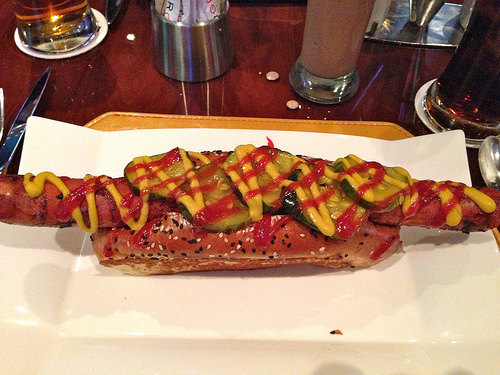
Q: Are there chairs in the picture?
A: No, there are no chairs.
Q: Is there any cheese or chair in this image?
A: No, there are no chairs or cheese.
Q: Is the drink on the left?
A: Yes, the drink is on the left of the image.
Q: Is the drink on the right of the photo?
A: No, the drink is on the left of the image.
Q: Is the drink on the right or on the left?
A: The drink is on the left of the image.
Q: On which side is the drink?
A: The drink is on the left of the image.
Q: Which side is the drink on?
A: The drink is on the left of the image.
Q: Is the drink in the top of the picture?
A: Yes, the drink is in the top of the image.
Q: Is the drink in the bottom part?
A: No, the drink is in the top of the image.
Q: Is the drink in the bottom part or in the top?
A: The drink is in the top of the image.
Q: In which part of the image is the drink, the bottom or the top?
A: The drink is in the top of the image.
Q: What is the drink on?
A: The drink is on the table.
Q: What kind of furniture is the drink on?
A: The drink is on the table.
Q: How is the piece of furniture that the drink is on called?
A: The piece of furniture is a table.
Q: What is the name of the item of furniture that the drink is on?
A: The piece of furniture is a table.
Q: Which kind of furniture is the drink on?
A: The drink is on the table.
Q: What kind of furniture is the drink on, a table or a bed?
A: The drink is on a table.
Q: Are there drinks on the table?
A: Yes, there is a drink on the table.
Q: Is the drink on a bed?
A: No, the drink is on the table.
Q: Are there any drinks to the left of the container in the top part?
A: Yes, there is a drink to the left of the container.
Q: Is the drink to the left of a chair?
A: No, the drink is to the left of the container.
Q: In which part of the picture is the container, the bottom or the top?
A: The container is in the top of the image.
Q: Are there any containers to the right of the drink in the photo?
A: Yes, there is a container to the right of the drink.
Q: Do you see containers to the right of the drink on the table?
A: Yes, there is a container to the right of the drink.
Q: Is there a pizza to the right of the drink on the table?
A: No, there is a container to the right of the drink.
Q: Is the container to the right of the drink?
A: Yes, the container is to the right of the drink.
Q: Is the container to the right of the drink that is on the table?
A: Yes, the container is to the right of the drink.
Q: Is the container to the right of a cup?
A: No, the container is to the right of the drink.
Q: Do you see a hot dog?
A: Yes, there is a hot dog.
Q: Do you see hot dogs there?
A: Yes, there is a hot dog.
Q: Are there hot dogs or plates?
A: Yes, there is a hot dog.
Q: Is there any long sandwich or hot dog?
A: Yes, there is a long hot dog.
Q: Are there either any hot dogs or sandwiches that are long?
A: Yes, the hot dog is long.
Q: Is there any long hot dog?
A: Yes, there is a long hot dog.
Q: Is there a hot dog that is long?
A: Yes, there is a hot dog that is long.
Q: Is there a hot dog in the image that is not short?
A: Yes, there is a long hot dog.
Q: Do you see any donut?
A: No, there are no donuts.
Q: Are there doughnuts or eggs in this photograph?
A: No, there are no doughnuts or eggs.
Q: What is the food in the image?
A: The food is a hot dog.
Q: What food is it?
A: The food is a hot dog.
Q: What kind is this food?
A: This is a hot dog.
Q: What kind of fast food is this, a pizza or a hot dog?
A: This is a hot dog.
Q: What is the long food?
A: The food is a hot dog.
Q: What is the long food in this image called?
A: The food is a hot dog.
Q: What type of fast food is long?
A: The fast food is a hot dog.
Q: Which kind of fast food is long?
A: The fast food is a hot dog.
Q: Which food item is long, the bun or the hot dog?
A: The hot dog is long.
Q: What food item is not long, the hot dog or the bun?
A: The bun is not long.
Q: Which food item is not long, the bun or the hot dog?
A: The bun is not long.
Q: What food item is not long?
A: The food item is a bun.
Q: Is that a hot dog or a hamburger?
A: That is a hot dog.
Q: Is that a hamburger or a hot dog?
A: That is a hot dog.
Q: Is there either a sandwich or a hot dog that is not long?
A: No, there is a hot dog but it is long.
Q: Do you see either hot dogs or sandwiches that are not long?
A: No, there is a hot dog but it is long.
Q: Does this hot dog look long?
A: Yes, the hot dog is long.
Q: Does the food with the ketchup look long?
A: Yes, the hot dog is long.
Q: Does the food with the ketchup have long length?
A: Yes, the hot dog is long.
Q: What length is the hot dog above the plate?
A: The hot dog is long.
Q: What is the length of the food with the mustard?
A: The hot dog is long.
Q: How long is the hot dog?
A: The hot dog is long.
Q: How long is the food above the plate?
A: The hot dog is long.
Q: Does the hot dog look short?
A: No, the hot dog is long.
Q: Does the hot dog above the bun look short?
A: No, the hot dog is long.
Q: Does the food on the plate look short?
A: No, the hot dog is long.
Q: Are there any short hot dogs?
A: No, there is a hot dog but it is long.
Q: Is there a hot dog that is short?
A: No, there is a hot dog but it is long.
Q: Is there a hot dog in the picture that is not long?
A: No, there is a hot dog but it is long.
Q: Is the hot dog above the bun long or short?
A: The hot dog is long.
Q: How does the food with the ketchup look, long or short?
A: The hot dog is long.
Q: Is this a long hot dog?
A: Yes, this is a long hot dog.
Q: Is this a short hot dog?
A: No, this is a long hot dog.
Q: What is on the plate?
A: The hot dog is on the plate.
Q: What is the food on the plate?
A: The food is a hot dog.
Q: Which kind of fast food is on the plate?
A: The food is a hot dog.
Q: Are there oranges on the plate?
A: No, there is a hot dog on the plate.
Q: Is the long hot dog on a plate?
A: Yes, the hot dog is on a plate.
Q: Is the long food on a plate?
A: Yes, the hot dog is on a plate.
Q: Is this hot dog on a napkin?
A: No, the hot dog is on a plate.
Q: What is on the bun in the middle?
A: The hot dog is on the bun.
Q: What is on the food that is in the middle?
A: The hot dog is on the bun.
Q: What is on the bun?
A: The hot dog is on the bun.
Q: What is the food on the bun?
A: The food is a hot dog.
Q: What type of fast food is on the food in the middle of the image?
A: The food is a hot dog.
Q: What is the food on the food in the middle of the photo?
A: The food is a hot dog.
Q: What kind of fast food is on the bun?
A: The food is a hot dog.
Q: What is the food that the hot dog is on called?
A: The food is a bun.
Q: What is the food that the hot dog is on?
A: The food is a bun.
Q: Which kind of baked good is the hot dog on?
A: The hot dog is on the bun.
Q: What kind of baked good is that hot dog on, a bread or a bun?
A: The hot dog is on a bun.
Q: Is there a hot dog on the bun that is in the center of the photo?
A: Yes, there is a hot dog on the bun.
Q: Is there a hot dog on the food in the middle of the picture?
A: Yes, there is a hot dog on the bun.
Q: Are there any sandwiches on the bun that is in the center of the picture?
A: No, there is a hot dog on the bun.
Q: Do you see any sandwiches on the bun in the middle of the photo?
A: No, there is a hot dog on the bun.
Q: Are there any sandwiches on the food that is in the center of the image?
A: No, there is a hot dog on the bun.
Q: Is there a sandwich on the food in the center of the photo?
A: No, there is a hot dog on the bun.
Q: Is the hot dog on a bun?
A: Yes, the hot dog is on a bun.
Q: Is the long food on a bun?
A: Yes, the hot dog is on a bun.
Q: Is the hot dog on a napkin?
A: No, the hot dog is on a bun.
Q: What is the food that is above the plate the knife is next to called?
A: The food is a hot dog.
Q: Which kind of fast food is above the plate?
A: The food is a hot dog.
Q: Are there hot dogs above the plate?
A: Yes, there is a hot dog above the plate.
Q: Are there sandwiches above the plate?
A: No, there is a hot dog above the plate.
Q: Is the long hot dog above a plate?
A: Yes, the hot dog is above a plate.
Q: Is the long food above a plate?
A: Yes, the hot dog is above a plate.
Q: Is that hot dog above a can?
A: No, the hot dog is above a plate.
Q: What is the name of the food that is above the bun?
A: The food is a hot dog.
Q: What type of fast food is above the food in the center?
A: The food is a hot dog.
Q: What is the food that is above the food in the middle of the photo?
A: The food is a hot dog.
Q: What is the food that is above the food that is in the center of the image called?
A: The food is a hot dog.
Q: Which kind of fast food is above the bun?
A: The food is a hot dog.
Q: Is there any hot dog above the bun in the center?
A: Yes, there is a hot dog above the bun.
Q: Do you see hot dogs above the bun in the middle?
A: Yes, there is a hot dog above the bun.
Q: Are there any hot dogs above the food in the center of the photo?
A: Yes, there is a hot dog above the bun.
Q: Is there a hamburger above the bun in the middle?
A: No, there is a hot dog above the bun.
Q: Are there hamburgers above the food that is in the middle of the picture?
A: No, there is a hot dog above the bun.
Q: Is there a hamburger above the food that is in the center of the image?
A: No, there is a hot dog above the bun.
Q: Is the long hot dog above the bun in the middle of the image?
A: Yes, the hot dog is above the bun.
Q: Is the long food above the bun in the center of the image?
A: Yes, the hot dog is above the bun.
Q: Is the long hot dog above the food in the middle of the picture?
A: Yes, the hot dog is above the bun.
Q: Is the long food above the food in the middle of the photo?
A: Yes, the hot dog is above the bun.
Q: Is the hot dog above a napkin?
A: No, the hot dog is above the bun.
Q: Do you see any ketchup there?
A: Yes, there is ketchup.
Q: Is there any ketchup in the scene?
A: Yes, there is ketchup.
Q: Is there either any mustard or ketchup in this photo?
A: Yes, there is ketchup.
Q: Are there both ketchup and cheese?
A: No, there is ketchup but no cheese.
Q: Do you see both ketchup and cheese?
A: No, there is ketchup but no cheese.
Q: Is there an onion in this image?
A: No, there are no onions.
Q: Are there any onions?
A: No, there are no onions.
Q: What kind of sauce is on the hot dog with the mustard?
A: The sauce is ketchup.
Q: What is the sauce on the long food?
A: The sauce is ketchup.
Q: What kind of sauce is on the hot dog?
A: The sauce is ketchup.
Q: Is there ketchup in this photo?
A: Yes, there is ketchup.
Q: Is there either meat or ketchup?
A: Yes, there is ketchup.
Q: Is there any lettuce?
A: No, there is no lettuce.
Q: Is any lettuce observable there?
A: No, there is no lettuce.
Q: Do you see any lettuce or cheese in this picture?
A: No, there are no lettuce or cheese.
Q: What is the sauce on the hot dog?
A: The sauce is ketchup.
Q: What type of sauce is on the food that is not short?
A: The sauce is ketchup.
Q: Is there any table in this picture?
A: Yes, there is a table.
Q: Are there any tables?
A: Yes, there is a table.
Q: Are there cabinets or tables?
A: Yes, there is a table.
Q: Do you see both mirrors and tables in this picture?
A: No, there is a table but no mirrors.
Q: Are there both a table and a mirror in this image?
A: No, there is a table but no mirrors.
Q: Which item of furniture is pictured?
A: The piece of furniture is a table.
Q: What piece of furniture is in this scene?
A: The piece of furniture is a table.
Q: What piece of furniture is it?
A: The piece of furniture is a table.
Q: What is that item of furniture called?
A: This is a table.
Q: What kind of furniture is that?
A: This is a table.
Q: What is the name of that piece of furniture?
A: This is a table.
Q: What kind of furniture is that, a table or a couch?
A: This is a table.